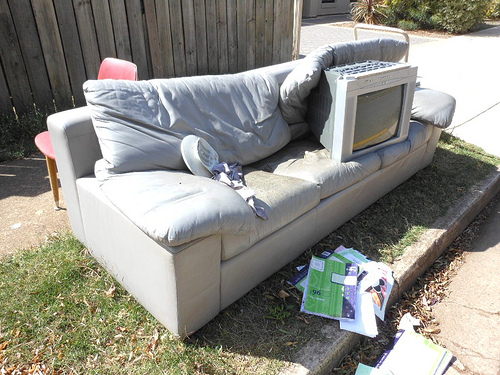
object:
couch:
[46, 35, 456, 341]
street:
[0, 27, 499, 373]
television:
[305, 59, 418, 164]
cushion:
[100, 170, 255, 244]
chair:
[34, 57, 137, 209]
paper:
[300, 253, 358, 321]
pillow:
[83, 75, 290, 174]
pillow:
[278, 36, 411, 136]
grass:
[0, 130, 499, 375]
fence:
[0, 0, 294, 126]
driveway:
[301, 16, 500, 132]